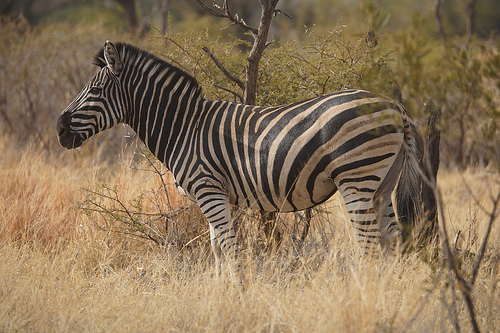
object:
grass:
[444, 189, 464, 213]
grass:
[5, 138, 41, 161]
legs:
[329, 173, 387, 288]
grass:
[167, 220, 419, 329]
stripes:
[136, 55, 155, 141]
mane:
[116, 36, 201, 86]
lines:
[326, 113, 398, 165]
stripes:
[342, 194, 373, 208]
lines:
[195, 187, 227, 202]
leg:
[183, 184, 250, 274]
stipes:
[243, 172, 300, 192]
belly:
[216, 153, 354, 234]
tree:
[290, 211, 323, 267]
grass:
[64, 245, 440, 332]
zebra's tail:
[399, 117, 455, 244]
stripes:
[202, 207, 229, 220]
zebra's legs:
[363, 170, 406, 285]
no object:
[432, 46, 489, 146]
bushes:
[78, 166, 297, 262]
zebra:
[52, 30, 452, 317]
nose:
[50, 104, 77, 135]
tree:
[204, 3, 281, 100]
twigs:
[470, 143, 497, 295]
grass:
[21, 169, 105, 294]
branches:
[112, 122, 177, 239]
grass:
[58, 136, 84, 180]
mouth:
[53, 107, 90, 152]